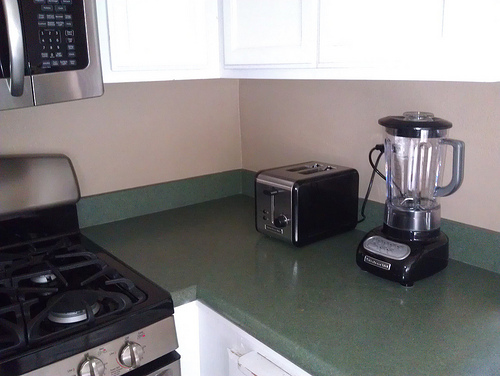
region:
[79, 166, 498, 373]
the counter top is green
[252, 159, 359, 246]
the toaster is black and silver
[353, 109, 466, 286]
the blender is black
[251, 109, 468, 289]
the blender is beside the toaster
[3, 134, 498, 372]
the stove is beside the counter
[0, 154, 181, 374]
the stove stop is black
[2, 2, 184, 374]
the microwave is above the stove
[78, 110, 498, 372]
the blender and toaster are on the counter top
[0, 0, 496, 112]
the cabinets are beside the microwave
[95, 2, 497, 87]
the cabinets are white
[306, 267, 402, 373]
the surface is made of arble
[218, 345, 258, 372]
the cabinets are white in oclor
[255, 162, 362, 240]
the heater is black in color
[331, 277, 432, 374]
the suface i s green in color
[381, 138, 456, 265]
the blender is on the surface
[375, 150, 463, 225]
blender is colorles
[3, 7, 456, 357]
a kitchen with white cabinets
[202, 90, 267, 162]
the corner of a kitchen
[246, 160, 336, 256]
a silver toaster on a counter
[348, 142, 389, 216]
the plug to a toaster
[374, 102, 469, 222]
the glass part of a blender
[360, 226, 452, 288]
the base of a blender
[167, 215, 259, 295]
the counter of a kitchen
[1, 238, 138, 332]
the burners on a stove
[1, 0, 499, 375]
Part of a kitchen with white cupboards.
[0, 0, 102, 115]
Microwave mounted above a stove.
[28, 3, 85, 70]
Numbers and push buttons on a black panel.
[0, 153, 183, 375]
Stainless steel stove with a black top.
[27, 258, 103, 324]
Gas burners on top of the stove.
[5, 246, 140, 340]
Black racks over the burners.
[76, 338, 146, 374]
Oven knobs.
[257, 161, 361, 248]
Stainless steel toaster with a black knob.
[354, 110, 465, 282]
Black blender with a clear container.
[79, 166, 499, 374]
Green kitchen countertops.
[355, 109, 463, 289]
Black and silver blender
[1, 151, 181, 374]
Silver stove underneath microwave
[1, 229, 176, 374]
Black stovetop with burners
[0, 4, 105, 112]
Silver and black microwave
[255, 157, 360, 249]
Silver and black toaster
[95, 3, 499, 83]
Windows above counter top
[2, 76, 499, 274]
Tan painted kitchen wall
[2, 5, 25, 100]
Door handle attached to microwave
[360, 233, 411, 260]
Speed setting buttons on blender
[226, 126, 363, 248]
A kitchen appliance on the counter.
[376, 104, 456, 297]
A kitchen appliance on the counter.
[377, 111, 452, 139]
black lid of a blender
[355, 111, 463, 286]
blender with black lid and base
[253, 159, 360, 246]
black and chrome metal toaster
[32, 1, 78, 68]
microwave oven control panel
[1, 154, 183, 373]
grey metal oven with chrome and black trim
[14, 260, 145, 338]
black gas stove plate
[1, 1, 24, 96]
a grey metal handle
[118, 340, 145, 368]
a shiny metal dial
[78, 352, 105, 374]
a shiny metal dial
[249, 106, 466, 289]
Toaster and blender on a kitchen counter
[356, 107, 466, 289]
blender on the counter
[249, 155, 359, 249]
toaster on a kitchen counter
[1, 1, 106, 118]
over-the-stove microwave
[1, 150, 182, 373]
stainless steel glass stove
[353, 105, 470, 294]
black blender on a green counter